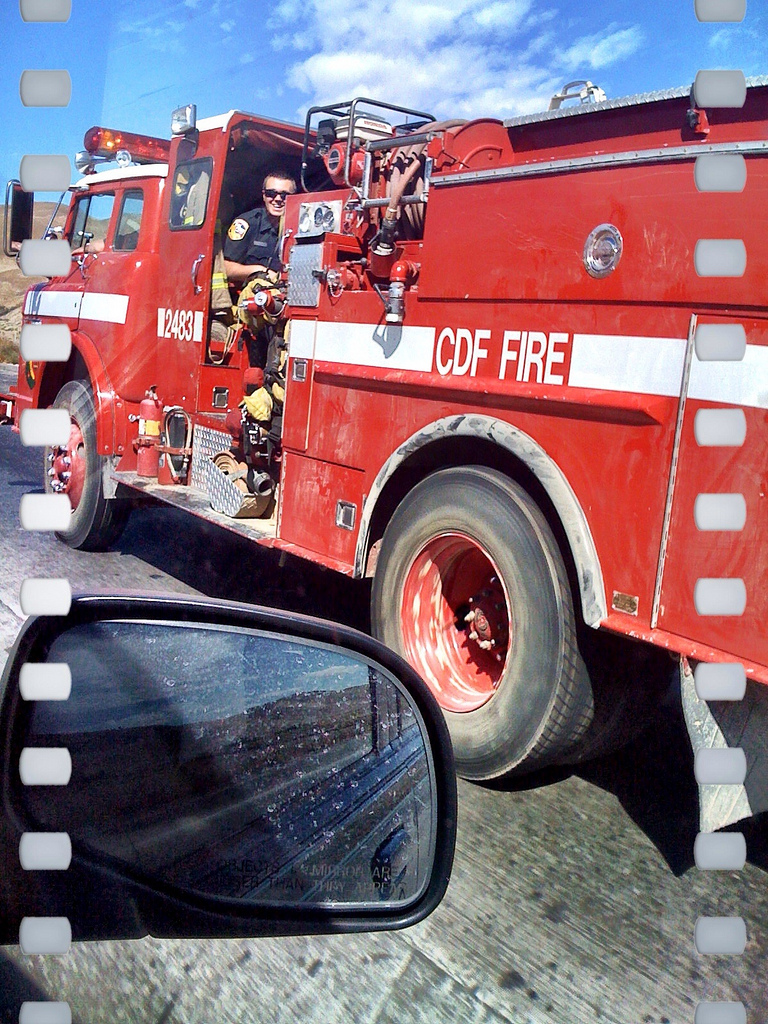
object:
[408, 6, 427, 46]
clouds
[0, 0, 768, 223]
sky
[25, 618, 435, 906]
reflection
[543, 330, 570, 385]
letter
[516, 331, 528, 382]
letter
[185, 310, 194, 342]
letter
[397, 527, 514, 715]
rim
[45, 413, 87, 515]
rim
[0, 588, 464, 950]
mirror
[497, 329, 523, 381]
letters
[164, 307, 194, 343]
number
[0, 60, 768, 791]
firetruck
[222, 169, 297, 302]
fireman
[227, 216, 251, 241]
patch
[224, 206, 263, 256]
shoulder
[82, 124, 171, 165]
light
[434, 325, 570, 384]
writing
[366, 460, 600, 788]
tire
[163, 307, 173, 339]
numbers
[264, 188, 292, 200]
glasses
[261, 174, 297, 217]
face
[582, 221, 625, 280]
tank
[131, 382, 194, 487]
extinguisher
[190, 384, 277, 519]
kit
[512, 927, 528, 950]
stains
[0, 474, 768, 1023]
ground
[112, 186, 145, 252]
windows